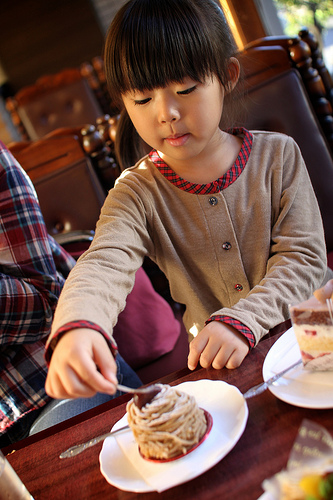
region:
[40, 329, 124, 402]
the hand of a girl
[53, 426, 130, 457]
part of a silver fork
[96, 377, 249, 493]
a small white plate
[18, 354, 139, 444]
part of a gray chair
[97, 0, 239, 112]
a girl's dark hair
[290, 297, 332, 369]
a piece of dessert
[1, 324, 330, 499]
part of a brown table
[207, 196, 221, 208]
a small shirt button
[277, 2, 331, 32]
green tree leaves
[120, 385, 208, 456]
a stack of spaghetti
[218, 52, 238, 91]
Child's ear under hair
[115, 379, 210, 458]
A dessert with spaghetti noodle shapes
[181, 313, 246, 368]
A child's hand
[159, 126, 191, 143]
a child's pursed lips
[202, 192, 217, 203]
Fasteners on a child's jacket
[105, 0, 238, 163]
a child's head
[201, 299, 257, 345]
plaid cuffs on a jacket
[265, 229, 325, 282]
a child's elbow in a jacket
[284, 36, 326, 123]
scroll work on a chair back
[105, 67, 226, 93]
a child's haircut with bangs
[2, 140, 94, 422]
plaid shirt of person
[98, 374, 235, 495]
white plate with dessert on it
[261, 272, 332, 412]
white plate with cake on it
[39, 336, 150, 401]
girl's hand holding spoon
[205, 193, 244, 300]
buttons on little girl's shirt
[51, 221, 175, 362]
pink pocketbook of woman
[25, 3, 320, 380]
little girl with dark hair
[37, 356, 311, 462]
three pieces of silverware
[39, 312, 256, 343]
red checked cuffs of little girl's shirt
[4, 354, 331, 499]
table desserts are on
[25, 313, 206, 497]
little girl is holding a fork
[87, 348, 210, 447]
girl is twirling spaghetti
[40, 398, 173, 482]
utensil on the plate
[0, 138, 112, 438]
person's shirt is plaid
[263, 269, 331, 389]
cake is on the plate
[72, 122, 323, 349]
girl's shirt is gray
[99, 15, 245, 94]
girl's bangs are above eyes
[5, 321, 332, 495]
the table is brown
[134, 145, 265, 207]
plaid pattern on girl's shirt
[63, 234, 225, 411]
red object behind person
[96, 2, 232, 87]
girl has straight brown hair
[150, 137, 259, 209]
girl has red and black checks on collar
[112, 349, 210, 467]
girl is twirling noodles on dish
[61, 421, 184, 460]
steel eating implement on plate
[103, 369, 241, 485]
plate is white and round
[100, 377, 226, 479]
white plate on brown table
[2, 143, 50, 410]
person with red and blue checked shirt next to girl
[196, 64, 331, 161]
blue cushion on girl's chair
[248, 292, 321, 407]
cake on plate next to noodle dish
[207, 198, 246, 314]
grey buttons on girl's shirt